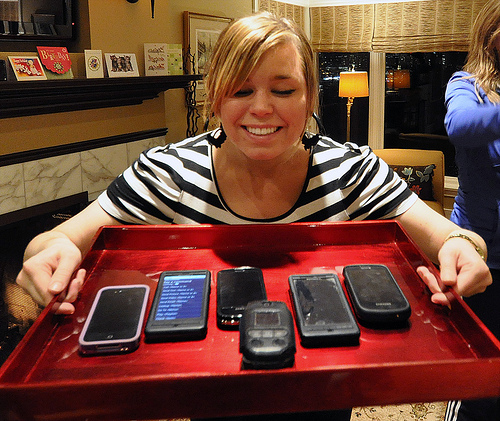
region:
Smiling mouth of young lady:
[230, 116, 288, 137]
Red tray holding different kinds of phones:
[5, 198, 483, 403]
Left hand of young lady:
[415, 236, 491, 306]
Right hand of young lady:
[16, 225, 92, 320]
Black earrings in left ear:
[297, 106, 329, 149]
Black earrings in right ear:
[197, 93, 234, 158]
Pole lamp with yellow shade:
[331, 58, 372, 143]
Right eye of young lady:
[220, 78, 255, 103]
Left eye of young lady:
[267, 80, 297, 100]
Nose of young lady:
[245, 94, 279, 124]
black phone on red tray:
[146, 265, 210, 340]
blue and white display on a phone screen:
[160, 273, 202, 320]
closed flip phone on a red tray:
[240, 298, 295, 362]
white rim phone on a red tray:
[78, 276, 150, 358]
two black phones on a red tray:
[293, 256, 416, 346]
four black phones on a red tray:
[213, 264, 411, 370]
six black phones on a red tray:
[88, 259, 415, 368]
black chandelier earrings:
[203, 111, 225, 151]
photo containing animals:
[104, 51, 139, 74]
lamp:
[339, 69, 369, 144]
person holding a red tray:
[8, 5, 498, 325]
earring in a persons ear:
[292, 105, 329, 159]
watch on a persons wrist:
[432, 227, 492, 268]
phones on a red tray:
[68, 254, 430, 376]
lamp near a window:
[330, 57, 381, 154]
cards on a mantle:
[75, 44, 144, 89]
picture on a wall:
[170, 6, 240, 114]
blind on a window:
[300, 0, 379, 60]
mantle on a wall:
[0, 66, 213, 127]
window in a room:
[307, 1, 376, 153]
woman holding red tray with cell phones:
[56, 61, 462, 359]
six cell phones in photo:
[77, 276, 422, 364]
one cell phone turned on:
[104, 262, 419, 367]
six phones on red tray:
[85, 193, 455, 419]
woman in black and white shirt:
[170, 102, 462, 278]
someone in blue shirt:
[407, 79, 498, 228]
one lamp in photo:
[330, 65, 396, 145]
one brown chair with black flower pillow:
[351, 136, 464, 253]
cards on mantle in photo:
[5, 30, 240, 107]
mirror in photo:
[6, 0, 116, 59]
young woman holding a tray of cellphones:
[14, 6, 493, 400]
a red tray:
[13, 213, 484, 401]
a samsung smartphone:
[351, 252, 401, 321]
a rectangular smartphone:
[286, 268, 363, 338]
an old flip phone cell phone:
[233, 297, 293, 369]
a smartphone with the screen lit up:
[145, 265, 212, 339]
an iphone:
[75, 274, 154, 358]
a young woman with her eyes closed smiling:
[194, 21, 326, 161]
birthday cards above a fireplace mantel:
[1, 20, 179, 112]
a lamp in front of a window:
[324, 60, 377, 168]